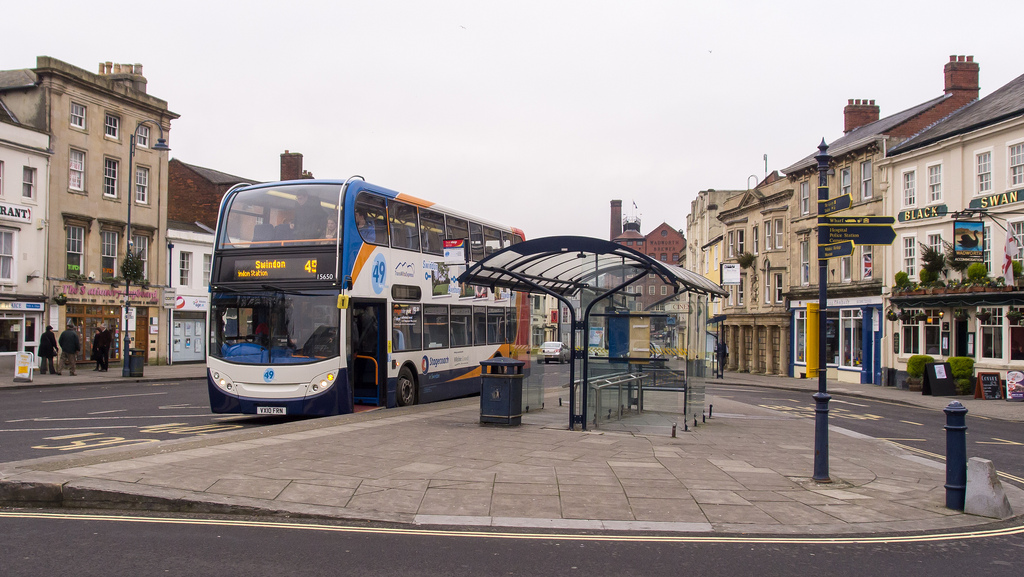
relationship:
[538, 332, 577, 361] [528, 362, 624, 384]
silver car on road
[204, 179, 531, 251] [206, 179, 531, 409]
top level of bus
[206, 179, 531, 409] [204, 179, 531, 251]
bus has top level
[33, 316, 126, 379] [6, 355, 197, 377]
people standing on a sidewalk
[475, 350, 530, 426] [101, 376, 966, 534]
black-trash can on ground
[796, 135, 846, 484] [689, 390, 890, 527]
black pole in sidewalk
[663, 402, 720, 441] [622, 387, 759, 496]
small-black stands in ground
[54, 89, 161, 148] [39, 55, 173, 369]
three windows on building front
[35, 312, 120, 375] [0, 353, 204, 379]
people on sidewalk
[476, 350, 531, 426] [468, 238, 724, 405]
black-trash can by a bus stop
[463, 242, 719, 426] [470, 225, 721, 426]
shelter at a bus stop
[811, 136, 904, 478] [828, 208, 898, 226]
sign tells street name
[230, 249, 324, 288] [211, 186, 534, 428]
destination on bus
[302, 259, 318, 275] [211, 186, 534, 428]
orange-bus numbers on bus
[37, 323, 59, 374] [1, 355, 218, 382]
people on sidewalk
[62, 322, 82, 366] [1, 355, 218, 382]
person on sidewalk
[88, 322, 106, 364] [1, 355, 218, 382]
person on sidewalk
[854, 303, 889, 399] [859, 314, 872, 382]
trim around door